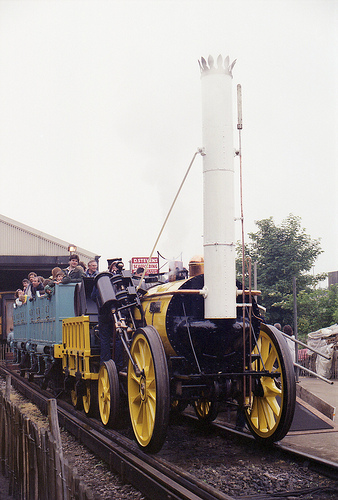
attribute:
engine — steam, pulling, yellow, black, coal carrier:
[40, 51, 306, 456]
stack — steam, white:
[193, 51, 245, 322]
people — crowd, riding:
[13, 247, 145, 311]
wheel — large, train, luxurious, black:
[124, 321, 175, 451]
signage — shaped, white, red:
[131, 256, 162, 277]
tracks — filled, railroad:
[1, 368, 335, 494]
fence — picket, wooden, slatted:
[1, 375, 72, 496]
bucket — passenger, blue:
[12, 277, 81, 345]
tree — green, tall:
[239, 210, 318, 307]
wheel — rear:
[97, 359, 120, 423]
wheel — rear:
[192, 399, 226, 422]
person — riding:
[85, 258, 100, 274]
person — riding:
[65, 255, 83, 269]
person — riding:
[31, 273, 46, 283]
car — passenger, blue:
[3, 245, 144, 372]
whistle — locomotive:
[163, 257, 184, 278]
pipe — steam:
[197, 48, 245, 312]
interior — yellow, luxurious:
[129, 335, 156, 438]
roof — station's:
[1, 208, 100, 267]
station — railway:
[1, 206, 100, 349]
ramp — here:
[298, 376, 337, 429]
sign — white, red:
[131, 258, 159, 279]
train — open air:
[8, 42, 304, 452]